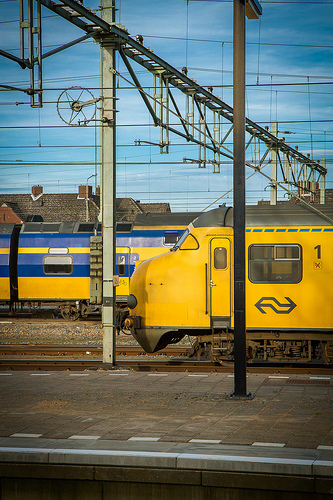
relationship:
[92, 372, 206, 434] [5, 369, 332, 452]
bricks on platform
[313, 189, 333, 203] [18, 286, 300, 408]
roof on track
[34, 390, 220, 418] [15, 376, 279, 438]
dirt on sidewalk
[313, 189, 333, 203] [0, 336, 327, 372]
roof on tracks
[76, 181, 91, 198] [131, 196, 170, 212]
chimney on roof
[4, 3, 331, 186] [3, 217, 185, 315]
wires above train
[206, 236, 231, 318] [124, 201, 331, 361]
door on yellow train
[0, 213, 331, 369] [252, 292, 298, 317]
train has diagram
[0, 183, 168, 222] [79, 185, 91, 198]
house has chimney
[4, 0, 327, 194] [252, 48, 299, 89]
sky with clouds